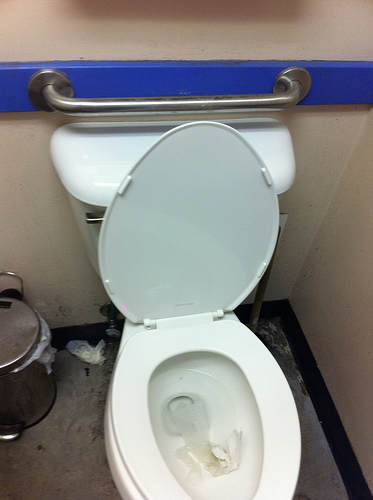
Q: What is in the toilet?
A: Toilet paper.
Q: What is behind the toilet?
A: A railing.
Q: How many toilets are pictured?
A: One.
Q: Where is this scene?
A: A bathroom.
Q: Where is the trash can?
A: To the left of the toilet.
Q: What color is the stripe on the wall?
A: Blue.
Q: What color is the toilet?
A: White.